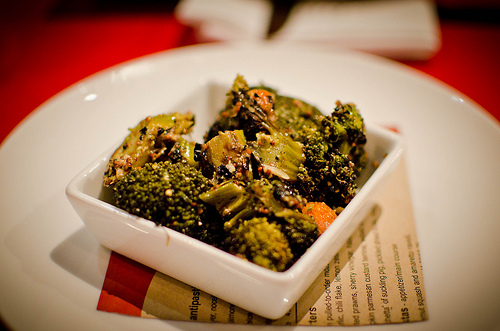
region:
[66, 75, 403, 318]
the shallow square bowl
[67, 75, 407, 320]
the small square bowl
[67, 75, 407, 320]
the white square bowl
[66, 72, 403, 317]
the food in the small square bowl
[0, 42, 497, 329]
the white round plate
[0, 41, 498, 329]
the plate is white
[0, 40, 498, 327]
the plate is round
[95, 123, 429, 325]
the paper under the square bowl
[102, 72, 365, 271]
the pile of green vegetables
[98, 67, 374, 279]
broccoli in square white plate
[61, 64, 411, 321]
porcelain square white plate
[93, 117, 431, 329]
piece of paper underneath white plate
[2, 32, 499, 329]
round white plate on table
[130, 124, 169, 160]
black and tan seasoning on top of broccoli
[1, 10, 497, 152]
red table cloth underneath whtie plate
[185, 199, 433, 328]
black type on piece of paper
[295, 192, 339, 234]
yellow-orange melted cheese on broccoli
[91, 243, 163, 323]
red stripe at top of paper underneath plate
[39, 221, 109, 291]
shadow on surface of white plate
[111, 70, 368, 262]
cooked broccoli in a small bowl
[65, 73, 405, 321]
a square white bowl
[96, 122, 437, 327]
a card under the bowl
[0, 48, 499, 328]
a white porcelain plate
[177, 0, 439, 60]
a white paper napkin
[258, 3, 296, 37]
a piece of silverware on the napkin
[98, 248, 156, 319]
red ink on the cardboard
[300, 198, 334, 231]
orange seasoning on the broccoli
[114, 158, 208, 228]
the head of a broccoli floret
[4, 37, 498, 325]
a plate made for dining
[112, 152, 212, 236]
veggie in a bowl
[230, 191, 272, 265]
veggie in a bowl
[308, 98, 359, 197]
veggie in a bowl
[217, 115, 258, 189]
veggie in a bowl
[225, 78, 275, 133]
veggie in a bowl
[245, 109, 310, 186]
veggie in a bowl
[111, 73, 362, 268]
a small portion of cooked broccoli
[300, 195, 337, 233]
a small round cooked carrot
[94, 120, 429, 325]
a square piece of paper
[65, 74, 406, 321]
a square white colored bowl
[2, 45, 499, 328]
a round white plate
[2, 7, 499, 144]
a red colored table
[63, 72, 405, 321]
a square bowl full of broccoli and a couple sliced carrots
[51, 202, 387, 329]
shadow of bowl on the paper and plate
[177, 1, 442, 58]
a folded white towel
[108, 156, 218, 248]
a green broccoli floret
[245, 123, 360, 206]
a green broccoli floret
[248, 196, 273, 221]
the grains of pepper are small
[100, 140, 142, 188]
spices on vegetables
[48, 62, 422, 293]
a bowl of broccoli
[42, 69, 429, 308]
the bowl is white